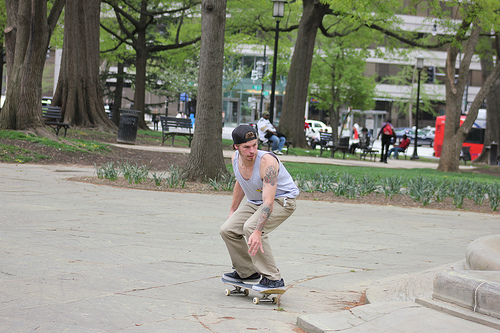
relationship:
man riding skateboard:
[218, 124, 301, 291] [223, 266, 294, 308]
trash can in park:
[113, 105, 145, 149] [22, 83, 411, 193]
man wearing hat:
[218, 124, 301, 291] [229, 122, 259, 146]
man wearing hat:
[207, 122, 297, 306] [228, 125, 261, 144]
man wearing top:
[218, 124, 301, 291] [229, 149, 299, 201]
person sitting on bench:
[257, 113, 285, 150] [244, 118, 305, 158]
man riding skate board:
[218, 124, 301, 291] [219, 275, 291, 308]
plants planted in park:
[327, 158, 484, 205] [49, 74, 491, 222]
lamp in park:
[268, 2, 286, 129] [1, 4, 497, 164]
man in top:
[218, 124, 301, 291] [228, 152, 308, 207]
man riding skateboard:
[218, 124, 301, 291] [196, 255, 311, 309]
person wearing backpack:
[374, 117, 403, 169] [378, 124, 398, 141]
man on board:
[218, 124, 301, 291] [213, 267, 295, 315]